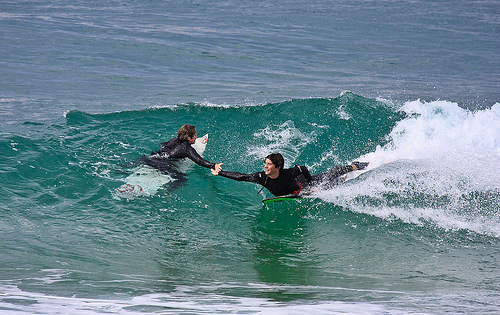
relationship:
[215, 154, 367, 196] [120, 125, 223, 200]
surfer highfives surfer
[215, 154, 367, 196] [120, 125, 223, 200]
surfer passing surfer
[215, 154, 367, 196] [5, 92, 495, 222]
surfer on wave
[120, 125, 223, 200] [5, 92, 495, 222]
surfer on wave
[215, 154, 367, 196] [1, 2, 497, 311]
surfer in water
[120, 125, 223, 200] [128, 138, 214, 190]
surfer in wet suit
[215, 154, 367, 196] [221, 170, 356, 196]
surfer in wet suit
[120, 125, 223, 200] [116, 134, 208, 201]
surfer on board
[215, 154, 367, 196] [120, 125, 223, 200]
surfer hitting surfer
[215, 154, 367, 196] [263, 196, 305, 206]
surfer on board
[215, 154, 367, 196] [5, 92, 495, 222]
surfer in wave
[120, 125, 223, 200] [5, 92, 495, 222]
surfer in wave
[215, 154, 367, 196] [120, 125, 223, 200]
surfer grabbing surfer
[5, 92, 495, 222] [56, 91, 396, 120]
wave has crest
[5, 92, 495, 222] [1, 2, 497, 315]
wave crashing water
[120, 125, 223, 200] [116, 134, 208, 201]
surfer straddling board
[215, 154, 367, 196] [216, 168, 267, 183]
surfer extends arm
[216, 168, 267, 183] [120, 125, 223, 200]
arm towards surfer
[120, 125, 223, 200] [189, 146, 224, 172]
surfer extends arm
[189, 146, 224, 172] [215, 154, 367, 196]
arm towards surfer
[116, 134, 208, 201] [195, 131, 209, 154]
board has nose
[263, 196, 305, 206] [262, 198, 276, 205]
board has nose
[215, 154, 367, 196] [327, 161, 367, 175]
surfer has foot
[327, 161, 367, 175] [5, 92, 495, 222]
foot falling towards wave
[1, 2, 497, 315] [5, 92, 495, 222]
water from wave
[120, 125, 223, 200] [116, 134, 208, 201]
surfer lying on board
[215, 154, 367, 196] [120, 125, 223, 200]
surfer holding surfer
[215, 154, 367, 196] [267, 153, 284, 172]
surfer wearing cap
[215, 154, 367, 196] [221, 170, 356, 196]
surfer wearing wet suit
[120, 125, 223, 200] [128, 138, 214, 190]
surfer wearing wet suit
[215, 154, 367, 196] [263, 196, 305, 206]
surfer has board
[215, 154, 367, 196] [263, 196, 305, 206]
surfer lying on board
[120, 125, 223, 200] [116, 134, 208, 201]
surfer sitting on board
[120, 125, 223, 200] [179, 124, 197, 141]
surfer has hair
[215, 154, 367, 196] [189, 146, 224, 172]
surfer touches arm